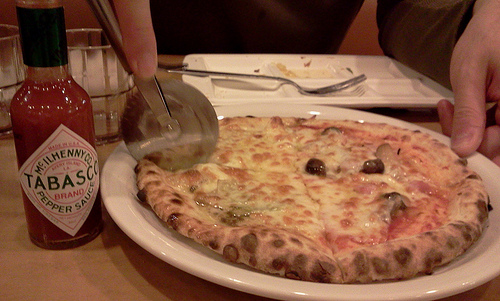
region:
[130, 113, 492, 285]
a pizza on a plate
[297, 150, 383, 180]
sausage on the pizza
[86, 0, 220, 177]
a pizza cutter cutting the pizza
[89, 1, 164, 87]
finger on the pizza cutter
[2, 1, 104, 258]
a jar of tabasco sauce by the pizza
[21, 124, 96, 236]
a label on the bottle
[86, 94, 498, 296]
the plate is white and round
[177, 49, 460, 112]
a tray behind the pizza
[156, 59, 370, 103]
a fork on the tray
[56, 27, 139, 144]
a glass behind the pizza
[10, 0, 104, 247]
Full bottle of Tabasco sauce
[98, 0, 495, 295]
Person slicing a whole pizza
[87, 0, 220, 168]
Silver round pizza cutter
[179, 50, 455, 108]
Empty dirty Styrofoam dinner plate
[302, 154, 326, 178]
Small sausage pizza topping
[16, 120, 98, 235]
Diamond label on a glass bottle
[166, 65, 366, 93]
Dirty silver dinner fork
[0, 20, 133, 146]
Two small glasses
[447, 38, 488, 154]
Thumb with a very short nail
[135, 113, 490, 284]
Round baked pizza cut in fours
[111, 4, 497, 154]
Human hands in the picture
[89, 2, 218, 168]
Pizza cutter in a hand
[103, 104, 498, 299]
Round plate on the table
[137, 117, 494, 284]
Pizza on the round plate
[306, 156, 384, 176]
Olives on the pizza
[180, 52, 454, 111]
Square plate on the table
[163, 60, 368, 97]
Fork on the square plate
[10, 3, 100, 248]
A bottle of pepper sauce on the table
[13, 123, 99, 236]
Label on the pepper sauce bottle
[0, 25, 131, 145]
Glasses on the table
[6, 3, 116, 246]
Tabasco hot sauce for dipping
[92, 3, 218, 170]
pizza cutter for slicing pizza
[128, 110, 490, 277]
cheese pizza for eating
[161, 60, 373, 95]
silver fork for eating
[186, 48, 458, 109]
white divided plate for food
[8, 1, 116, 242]
hot sauce for pizza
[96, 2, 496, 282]
man cutting pizza into halves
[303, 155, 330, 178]
sausage topping on pizza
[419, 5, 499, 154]
person holding end of plate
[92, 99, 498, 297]
tan plate with pizza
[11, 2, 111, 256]
a bottle of Tabasco sauce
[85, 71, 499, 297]
white plate with pizza in it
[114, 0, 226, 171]
silver colored metal pizza cutter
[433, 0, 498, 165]
person's left thumb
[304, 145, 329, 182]
black olive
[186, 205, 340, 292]
crust on pizza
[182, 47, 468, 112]
white tray with fork sitting on it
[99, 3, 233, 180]
finger on the pizza cutter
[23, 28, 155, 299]
clear glass sitting on table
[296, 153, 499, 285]
slice of pizza